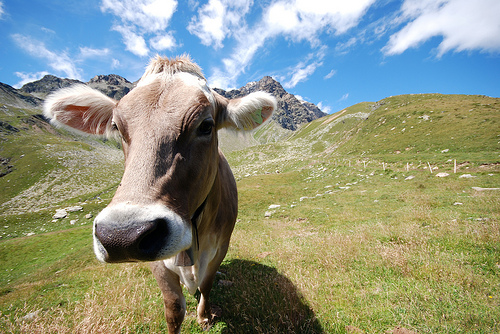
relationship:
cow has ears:
[39, 52, 287, 331] [42, 82, 287, 145]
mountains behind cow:
[0, 63, 339, 139] [39, 52, 287, 331]